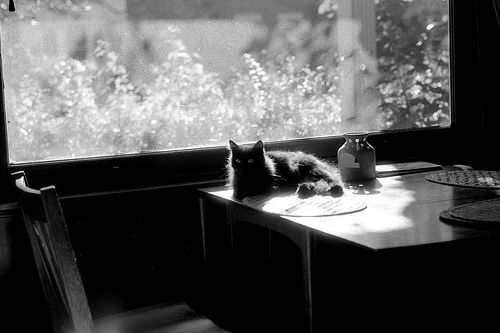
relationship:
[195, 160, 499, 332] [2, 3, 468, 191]
table next to window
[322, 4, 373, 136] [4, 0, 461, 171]
pole outside window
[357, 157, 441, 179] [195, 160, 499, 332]
papers on table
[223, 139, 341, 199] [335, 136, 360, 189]
cat next to jar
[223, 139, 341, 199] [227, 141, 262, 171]
cat has eyes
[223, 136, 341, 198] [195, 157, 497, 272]
cat on table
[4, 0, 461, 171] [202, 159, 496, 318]
window above table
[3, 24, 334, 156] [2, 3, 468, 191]
bush outside window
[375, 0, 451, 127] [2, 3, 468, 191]
bush outside window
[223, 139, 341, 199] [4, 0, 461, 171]
cat by window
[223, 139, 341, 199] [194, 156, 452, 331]
cat lying on table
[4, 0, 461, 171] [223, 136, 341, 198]
window behind cat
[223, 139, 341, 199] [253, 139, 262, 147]
cat has ear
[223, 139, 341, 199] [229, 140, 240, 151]
cat has ear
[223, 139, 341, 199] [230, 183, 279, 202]
cat has legs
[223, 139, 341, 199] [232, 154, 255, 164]
cat has eyes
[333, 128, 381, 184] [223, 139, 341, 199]
jar next to cat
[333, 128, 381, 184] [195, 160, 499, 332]
jar on table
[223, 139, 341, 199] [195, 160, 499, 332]
cat on table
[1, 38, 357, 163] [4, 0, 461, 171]
foliage through window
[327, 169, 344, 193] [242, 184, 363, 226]
rear paw on placemat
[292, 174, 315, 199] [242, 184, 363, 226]
rear paw on placemat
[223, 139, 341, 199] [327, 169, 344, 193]
cat has rear paw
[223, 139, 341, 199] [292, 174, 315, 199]
cat has rear paw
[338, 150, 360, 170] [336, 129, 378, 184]
label on jar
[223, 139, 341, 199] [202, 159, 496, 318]
cat on table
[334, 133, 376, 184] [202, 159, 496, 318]
jar on table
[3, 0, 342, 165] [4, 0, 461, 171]
bush outside window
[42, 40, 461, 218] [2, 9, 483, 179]
sun coming through window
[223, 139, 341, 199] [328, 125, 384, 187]
cat and jar